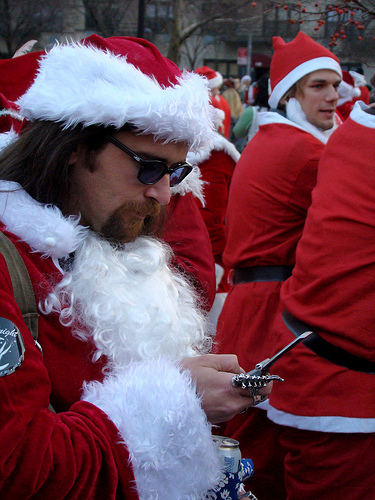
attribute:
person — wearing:
[265, 99, 372, 498]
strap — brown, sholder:
[0, 231, 43, 357]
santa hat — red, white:
[337, 71, 361, 97]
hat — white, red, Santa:
[3, 25, 217, 151]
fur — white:
[15, 38, 214, 155]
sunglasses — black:
[108, 125, 190, 186]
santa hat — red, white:
[15, 33, 211, 139]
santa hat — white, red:
[266, 30, 341, 109]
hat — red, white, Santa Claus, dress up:
[0, 23, 222, 120]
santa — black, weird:
[8, 10, 245, 416]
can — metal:
[208, 432, 244, 475]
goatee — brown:
[101, 200, 173, 248]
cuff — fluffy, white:
[197, 129, 242, 163]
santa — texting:
[5, 25, 280, 498]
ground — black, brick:
[281, 95, 312, 125]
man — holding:
[16, 33, 215, 323]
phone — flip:
[230, 328, 313, 387]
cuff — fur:
[84, 369, 229, 494]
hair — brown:
[2, 113, 110, 186]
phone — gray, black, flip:
[237, 327, 312, 380]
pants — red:
[257, 399, 374, 491]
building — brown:
[4, 2, 363, 49]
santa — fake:
[0, 36, 244, 497]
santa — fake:
[278, 90, 363, 498]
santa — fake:
[242, 32, 345, 215]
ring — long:
[228, 373, 286, 390]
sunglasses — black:
[108, 126, 215, 199]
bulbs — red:
[228, 355, 279, 391]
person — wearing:
[13, 36, 230, 410]